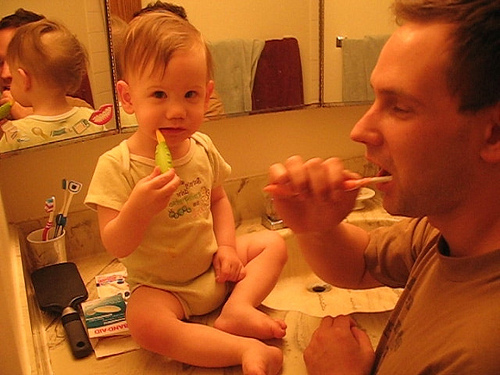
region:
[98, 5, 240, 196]
child brushing teeth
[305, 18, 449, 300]
man brushing his teeth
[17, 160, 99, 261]
cup with toothbrushes in it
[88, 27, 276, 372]
child sitting on bathroom sink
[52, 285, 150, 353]
box of band aids on counter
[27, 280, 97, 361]
black hair brush on counter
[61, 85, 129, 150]
sticker on mirror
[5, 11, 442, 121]
three mirrors over sink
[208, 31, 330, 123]
two towels reflected in mirror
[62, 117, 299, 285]
child wearing a onesie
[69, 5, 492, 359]
Father and son brushing their teeth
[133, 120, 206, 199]
Little boy's toothbrush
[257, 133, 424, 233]
Father's toothbrush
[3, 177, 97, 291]
Toothbrushes not being used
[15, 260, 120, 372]
Hairbrush on the counter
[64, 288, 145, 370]
Box of band-aid's on the counter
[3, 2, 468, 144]
Mirror in the background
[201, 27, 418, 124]
Reflection of towels in the mirror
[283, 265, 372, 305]
Drain in the sink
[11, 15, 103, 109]
Reflection of little boy's head in the mirror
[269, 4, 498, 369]
a man brushing his teeth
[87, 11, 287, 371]
a chid sitting on a counter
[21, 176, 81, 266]
a cup of toothbrushes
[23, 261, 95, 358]
a black hair brush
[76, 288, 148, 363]
a box of bandages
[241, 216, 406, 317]
a bathroom sink basin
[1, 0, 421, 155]
three wall mounted mirrors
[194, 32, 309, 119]
reflection of towels on a bar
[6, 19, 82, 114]
reflection of back of baby's head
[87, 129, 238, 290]
a babys' white top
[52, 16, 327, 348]
young child brushing his teeth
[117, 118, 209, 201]
bright green and yellow toothbrush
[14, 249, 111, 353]
large black hair brush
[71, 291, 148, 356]
box of bandaids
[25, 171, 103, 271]
cup of toothbrushes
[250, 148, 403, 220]
orange and white toothbrush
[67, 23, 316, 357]
a baby wearing a onsie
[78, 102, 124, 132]
a lips sticker on the mirror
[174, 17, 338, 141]
relfection of towels in the mirror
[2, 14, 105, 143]
reflection of child in mirror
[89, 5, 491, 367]
man and child brushing teeth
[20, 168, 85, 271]
toothbrush holder on bathroom counter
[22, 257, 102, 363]
hairbrush bristle side down on counter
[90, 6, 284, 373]
young child without pants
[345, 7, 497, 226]
man with no facial hair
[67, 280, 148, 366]
box of band aids on bathroom counter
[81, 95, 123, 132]
sticker of lips and teeth on mirror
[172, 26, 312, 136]
reflection of towels hanging on bar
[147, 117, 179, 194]
toddler toothbrush with easy grip handle